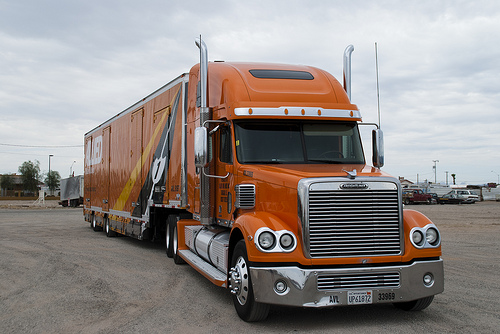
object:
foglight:
[423, 270, 434, 285]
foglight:
[273, 280, 287, 292]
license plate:
[346, 287, 375, 307]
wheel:
[98, 208, 113, 237]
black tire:
[227, 235, 269, 325]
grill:
[305, 176, 405, 257]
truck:
[75, 34, 447, 323]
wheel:
[87, 208, 100, 228]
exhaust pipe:
[343, 45, 356, 98]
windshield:
[234, 117, 362, 164]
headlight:
[256, 226, 277, 248]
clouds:
[451, 9, 499, 30]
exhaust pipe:
[193, 38, 211, 220]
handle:
[198, 168, 239, 189]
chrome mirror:
[192, 117, 207, 174]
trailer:
[71, 62, 202, 251]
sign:
[151, 155, 167, 183]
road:
[7, 304, 75, 331]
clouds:
[24, 12, 80, 49]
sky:
[441, 17, 487, 38]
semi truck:
[182, 37, 443, 320]